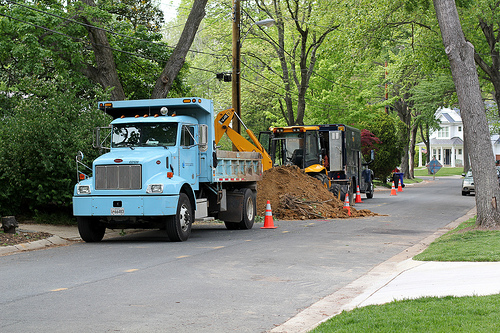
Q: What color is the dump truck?
A: Light blue.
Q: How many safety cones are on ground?
A: Five.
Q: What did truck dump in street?
A: Dirt.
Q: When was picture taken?
A: Daytime.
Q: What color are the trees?
A: Green.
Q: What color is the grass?
A: Green.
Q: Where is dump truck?
A: On the street.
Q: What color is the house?
A: White.